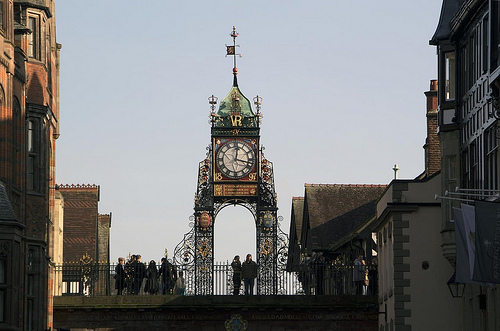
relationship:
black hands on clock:
[233, 146, 250, 165] [215, 139, 255, 179]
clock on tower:
[215, 139, 255, 179] [192, 26, 278, 293]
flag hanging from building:
[447, 200, 494, 294] [422, 1, 497, 329]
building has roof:
[282, 170, 402, 329] [285, 130, 404, 283]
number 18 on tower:
[212, 170, 223, 181] [203, 23, 274, 235]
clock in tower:
[216, 137, 254, 183] [166, 23, 304, 295]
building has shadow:
[2, 2, 66, 329] [2, 57, 52, 330]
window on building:
[441, 49, 455, 100] [437, 0, 500, 330]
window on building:
[445, 155, 458, 211] [437, 0, 500, 330]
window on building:
[23, 12, 40, 58] [2, 0, 62, 330]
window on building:
[22, 116, 44, 188] [2, 0, 62, 330]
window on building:
[26, 243, 39, 324] [2, 0, 62, 330]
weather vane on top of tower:
[224, 22, 244, 95] [189, 22, 284, 297]